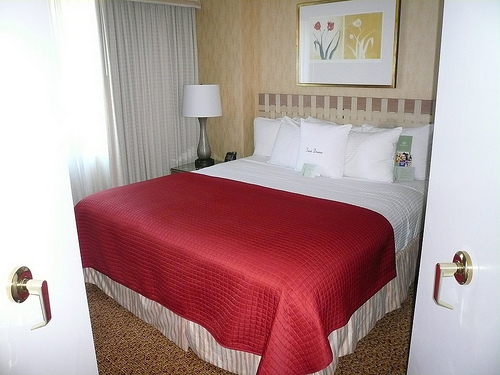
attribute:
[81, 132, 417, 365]
bed — made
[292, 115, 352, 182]
pillow — white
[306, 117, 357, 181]
pillow — bed, writing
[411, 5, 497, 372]
doors — double, open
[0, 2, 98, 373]
doors — open, double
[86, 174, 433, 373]
quilt — red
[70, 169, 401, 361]
bedspread — red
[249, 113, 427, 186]
pillows — white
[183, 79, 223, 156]
lamp — white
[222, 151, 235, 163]
clock — small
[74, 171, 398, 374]
bed spread — red, white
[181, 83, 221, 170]
lamp — white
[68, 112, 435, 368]
bed — queen sized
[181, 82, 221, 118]
shade — white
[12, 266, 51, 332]
handle — golden